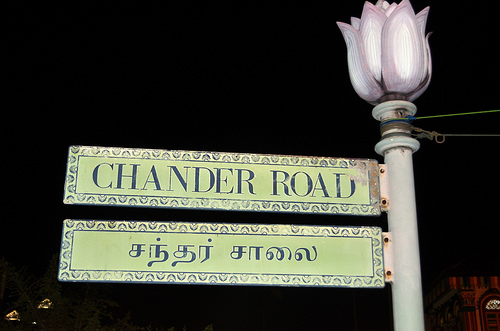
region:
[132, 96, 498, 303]
sign on a pole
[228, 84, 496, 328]
sign on a metal pole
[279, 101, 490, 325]
a pole with a sign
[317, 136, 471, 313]
a metal pole with a sign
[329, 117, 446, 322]
a street sign on a ople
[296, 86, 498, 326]
street sign on a metal pole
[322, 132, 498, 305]
pole with a street sign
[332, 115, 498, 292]
metal pole with street sign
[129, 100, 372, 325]
two street signs on a pole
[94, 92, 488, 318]
two street signs on a metal pole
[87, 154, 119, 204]
C on a sign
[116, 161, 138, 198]
H on a sign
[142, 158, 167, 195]
Blue A on a sign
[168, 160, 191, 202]
Blue N on a sign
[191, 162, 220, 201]
Blue D on a sign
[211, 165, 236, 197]
Blue E on a sign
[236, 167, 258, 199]
Blue R on a sign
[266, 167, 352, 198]
Blue "Road" written on a sign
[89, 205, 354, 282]
Blue street sign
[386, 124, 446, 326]
Pole holding up a street sign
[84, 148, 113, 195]
Blue letter on a grene street sign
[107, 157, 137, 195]
Blue letter on a grene street sign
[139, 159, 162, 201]
Blue letter on a grene street sign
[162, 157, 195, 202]
Blue letter on a grene street sign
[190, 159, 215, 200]
Blue letter on a grene street sign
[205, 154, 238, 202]
Blue letter on a grene street sign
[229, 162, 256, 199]
Blue letter on a grene street sign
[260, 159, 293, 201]
Blue letter on a grene street sign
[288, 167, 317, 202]
Blue letter on a grene street sign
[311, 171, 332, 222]
Blue letter on a grene street sign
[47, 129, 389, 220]
the street sign for CHANDER ROAD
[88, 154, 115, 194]
the letter C on a sign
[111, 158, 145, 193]
the letter H on a sign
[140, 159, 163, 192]
the letter A on a sign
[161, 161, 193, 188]
the letter N on a sign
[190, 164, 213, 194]
the letter D on a sign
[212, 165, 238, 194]
the letter E on a sign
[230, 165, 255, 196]
the letter R on a sign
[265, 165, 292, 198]
the letter R on a sign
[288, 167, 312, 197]
the letter O on a sign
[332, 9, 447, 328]
A lamp post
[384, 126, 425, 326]
The post is made of metal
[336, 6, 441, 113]
The top looks like a flower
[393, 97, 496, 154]
Wires connected to the post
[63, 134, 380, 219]
This is Chander Road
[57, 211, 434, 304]
Street sign not in English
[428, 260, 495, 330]
A small building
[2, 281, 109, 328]
A house with lights on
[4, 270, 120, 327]
There is a tree in front of the house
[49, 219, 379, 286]
This sign is below the Chander Road sign